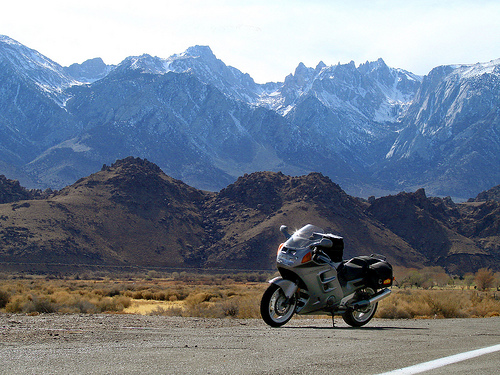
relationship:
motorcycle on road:
[258, 222, 396, 337] [1, 309, 500, 373]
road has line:
[1, 309, 500, 373] [374, 341, 499, 371]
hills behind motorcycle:
[1, 155, 500, 291] [258, 222, 396, 337]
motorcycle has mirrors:
[258, 222, 396, 337] [310, 237, 333, 249]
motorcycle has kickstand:
[258, 222, 396, 337] [330, 308, 337, 327]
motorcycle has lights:
[258, 222, 396, 337] [280, 245, 297, 257]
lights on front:
[280, 245, 297, 257] [261, 223, 318, 327]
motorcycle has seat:
[258, 222, 396, 337] [337, 257, 375, 281]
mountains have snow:
[2, 36, 499, 198] [1, 34, 496, 125]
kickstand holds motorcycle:
[330, 308, 337, 327] [258, 222, 396, 337]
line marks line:
[374, 341, 499, 371] [374, 341, 499, 375]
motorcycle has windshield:
[258, 222, 396, 337] [284, 223, 322, 249]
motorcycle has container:
[258, 222, 396, 337] [366, 262, 393, 288]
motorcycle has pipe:
[258, 222, 396, 337] [351, 289, 391, 306]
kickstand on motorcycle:
[330, 308, 337, 327] [258, 222, 396, 337]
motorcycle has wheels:
[258, 222, 396, 337] [259, 278, 300, 329]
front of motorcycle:
[261, 223, 318, 327] [258, 222, 396, 337]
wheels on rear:
[259, 278, 300, 329] [342, 255, 394, 324]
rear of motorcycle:
[342, 255, 394, 324] [258, 222, 396, 337]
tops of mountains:
[2, 37, 498, 120] [2, 36, 499, 198]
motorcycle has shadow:
[258, 222, 396, 337] [286, 321, 426, 332]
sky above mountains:
[6, 1, 499, 74] [2, 36, 499, 198]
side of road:
[4, 312, 343, 350] [1, 309, 500, 373]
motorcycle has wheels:
[258, 222, 396, 337] [259, 278, 377, 325]